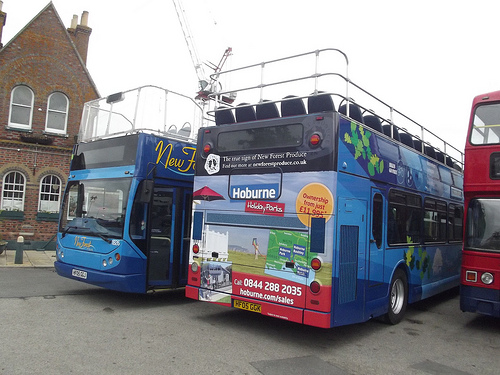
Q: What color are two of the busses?
A: Blue.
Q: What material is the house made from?
A: Brick.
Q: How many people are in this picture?
A: Zero.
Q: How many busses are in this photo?
A: Three.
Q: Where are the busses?
A: In the street.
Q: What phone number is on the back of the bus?
A: 0844 288 2035.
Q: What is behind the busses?
A: A crane.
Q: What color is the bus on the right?
A: Red.